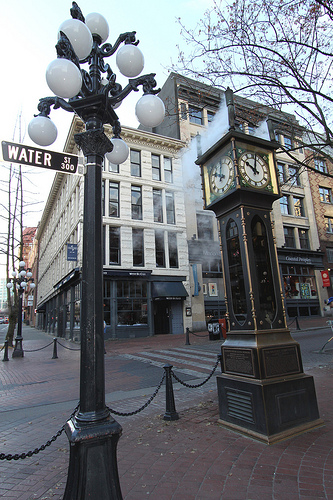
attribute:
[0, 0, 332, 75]
sky — blue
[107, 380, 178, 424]
metal chain — black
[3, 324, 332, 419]
street — black, white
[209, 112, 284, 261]
tower — black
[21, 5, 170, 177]
globes — white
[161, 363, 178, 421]
post — black 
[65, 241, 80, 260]
flag — blue, white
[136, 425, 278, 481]
sidewalk — cobblestone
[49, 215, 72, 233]
pavers — square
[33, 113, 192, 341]
building — white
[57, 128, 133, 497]
post — black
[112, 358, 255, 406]
chain — black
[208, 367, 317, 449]
base — tower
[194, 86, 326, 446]
tower — clock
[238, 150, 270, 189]
clock — face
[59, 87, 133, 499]
pole — black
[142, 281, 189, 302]
awning — black